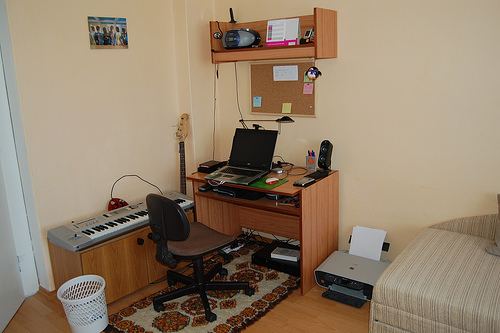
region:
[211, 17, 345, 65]
the shelf above the desk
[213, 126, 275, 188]
the laptop on the desk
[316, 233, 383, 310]
the printer on the floor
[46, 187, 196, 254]
the keyboard on the cabinet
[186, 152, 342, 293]
the desk in the corner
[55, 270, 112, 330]
the trash can by the cabinet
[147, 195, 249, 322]
the office chair by the desk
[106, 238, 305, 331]
the rug under the chair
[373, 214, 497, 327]
the chair by the printer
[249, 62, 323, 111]
the corkboard above the desk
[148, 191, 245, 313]
a chair at a desk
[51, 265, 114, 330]
a white hamper by a cupboard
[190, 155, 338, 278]
a brown wooden desk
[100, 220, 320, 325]
a flowered rug under a chair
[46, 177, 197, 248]
a keyboard on a cupboard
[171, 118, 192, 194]
a guitar in a corner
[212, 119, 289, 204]
a laptop on a desk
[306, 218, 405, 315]
a printer on the floor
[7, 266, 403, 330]
a brown wood floor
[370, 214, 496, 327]
a striped couch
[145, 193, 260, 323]
office chair on wheels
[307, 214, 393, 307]
printer with white paper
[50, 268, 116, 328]
small white wastepaper basket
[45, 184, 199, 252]
silver keyboard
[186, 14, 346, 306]
desk in a home office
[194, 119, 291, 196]
black laptop on a desk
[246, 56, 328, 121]
bulletin board with post-its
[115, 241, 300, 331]
orange white and black floor rug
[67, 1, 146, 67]
small poster hung on the wall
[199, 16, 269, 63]
boombox on a shelf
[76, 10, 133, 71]
a picture on a wall.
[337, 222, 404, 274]
paper in a printer.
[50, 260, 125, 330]
a small white trash can.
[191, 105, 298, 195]
an open laptop computer.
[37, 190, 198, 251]
a musical keyboard.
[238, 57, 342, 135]
a small bulletin board.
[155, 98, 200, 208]
an electric guitar.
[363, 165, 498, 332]
a bed with a blanket on it.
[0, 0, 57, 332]
an open door.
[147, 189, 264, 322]
a computer desk chair.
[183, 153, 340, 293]
a wooden computer desk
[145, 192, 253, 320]
a small office chair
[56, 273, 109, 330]
a white waste basket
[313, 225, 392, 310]
a printer sitting on the floor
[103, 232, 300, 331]
a colorful rug on the floor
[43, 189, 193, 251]
an electronic keyboard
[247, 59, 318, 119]
a small bulletin board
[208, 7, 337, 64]
a shelf above the desk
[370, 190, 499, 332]
a couch next to the desk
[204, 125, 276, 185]
a laptop computer